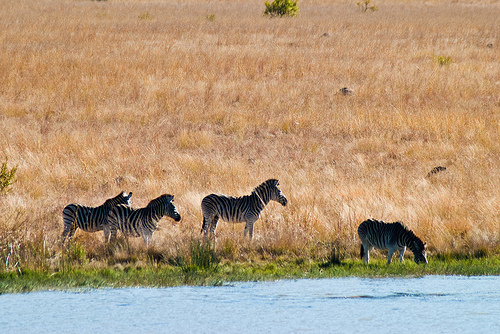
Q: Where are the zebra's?
A: Grass plain.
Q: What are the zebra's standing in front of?
A: Body of water.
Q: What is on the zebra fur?
A: Striped pattern.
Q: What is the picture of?
A: A few zebras on the riverbank.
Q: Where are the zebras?
A: In grass on a riverbank.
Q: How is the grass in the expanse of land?
A: Grass on the expanse of land is tall, dry and brown.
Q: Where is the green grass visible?
A: Green grass is on the riverbank near the water of the river.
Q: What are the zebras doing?
A: Three zebras are standing and looking on while one zebra is drinking river water.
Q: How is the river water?
A: Blue and clean.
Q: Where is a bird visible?
A: A bird is in the grass behind the zebra that is drinking water.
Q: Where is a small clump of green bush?
A: At the far end of the brown grassy expanse.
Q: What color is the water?
A: Blue.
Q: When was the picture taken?
A: Daytime.